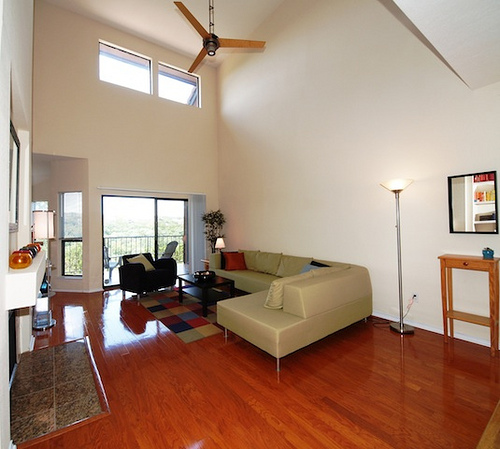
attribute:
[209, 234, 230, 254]
lamp — white, small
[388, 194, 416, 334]
pole — silver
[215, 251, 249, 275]
pillow — red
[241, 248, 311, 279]
cushion — tan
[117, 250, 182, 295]
chair — black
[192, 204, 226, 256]
plant — in a pot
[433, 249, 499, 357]
wooden table — brown, small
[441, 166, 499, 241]
mirror — black framed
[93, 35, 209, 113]
window — inside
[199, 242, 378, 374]
sofa — beige, sectional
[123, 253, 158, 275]
pillow — beige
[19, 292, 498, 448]
floor — hard wood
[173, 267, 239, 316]
coffee table — black, centered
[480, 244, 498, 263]
container — blue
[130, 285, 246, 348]
rug — colorful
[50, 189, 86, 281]
window — inside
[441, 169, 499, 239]
frame — black